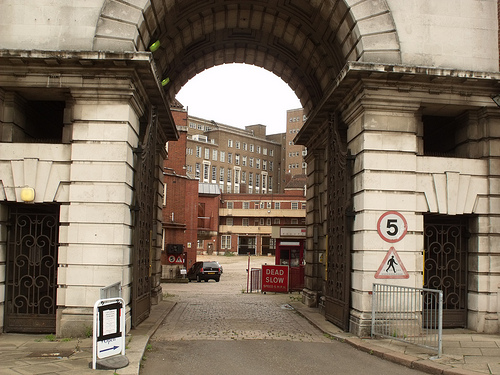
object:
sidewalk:
[0, 327, 143, 374]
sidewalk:
[361, 322, 500, 374]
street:
[137, 255, 469, 374]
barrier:
[365, 279, 450, 361]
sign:
[87, 295, 131, 375]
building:
[2, 0, 499, 375]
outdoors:
[2, 1, 499, 374]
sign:
[260, 264, 291, 294]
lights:
[141, 36, 167, 56]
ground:
[407, 134, 487, 212]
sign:
[373, 245, 411, 281]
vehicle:
[185, 259, 224, 283]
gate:
[0, 196, 64, 339]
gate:
[419, 207, 484, 337]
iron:
[432, 242, 459, 287]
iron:
[17, 220, 49, 295]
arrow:
[96, 343, 121, 354]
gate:
[322, 111, 358, 335]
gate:
[128, 111, 162, 332]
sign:
[376, 208, 410, 244]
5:
[386, 218, 399, 237]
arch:
[115, 0, 391, 350]